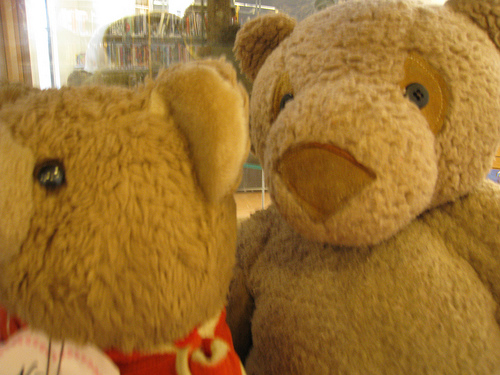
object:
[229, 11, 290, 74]
ear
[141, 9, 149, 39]
books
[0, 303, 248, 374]
shirt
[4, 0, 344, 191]
window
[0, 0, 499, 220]
background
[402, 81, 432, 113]
button eye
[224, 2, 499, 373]
teddy bear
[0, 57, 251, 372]
teddy bear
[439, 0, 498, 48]
ears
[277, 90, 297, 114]
eye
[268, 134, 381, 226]
nose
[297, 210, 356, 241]
mouth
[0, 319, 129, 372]
patch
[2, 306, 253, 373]
outfit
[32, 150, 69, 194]
eye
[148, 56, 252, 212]
ear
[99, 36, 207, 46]
shelves